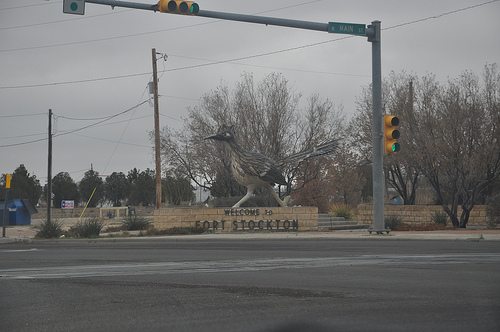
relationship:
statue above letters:
[207, 124, 344, 208] [196, 207, 300, 232]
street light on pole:
[383, 113, 400, 156] [86, 1, 392, 234]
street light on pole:
[159, 1, 199, 17] [86, 1, 392, 234]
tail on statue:
[273, 138, 339, 166] [207, 124, 344, 208]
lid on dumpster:
[21, 197, 39, 215] [1, 199, 38, 225]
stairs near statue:
[318, 210, 370, 232] [207, 124, 344, 208]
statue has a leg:
[207, 124, 344, 208] [232, 183, 257, 209]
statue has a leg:
[207, 124, 344, 208] [267, 184, 290, 208]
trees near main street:
[147, 62, 499, 228] [0, 235, 500, 331]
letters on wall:
[196, 207, 300, 232] [33, 206, 320, 231]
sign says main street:
[326, 22, 368, 36] [339, 24, 364, 32]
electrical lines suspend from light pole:
[2, 0, 499, 149] [151, 47, 164, 206]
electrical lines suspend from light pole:
[2, 0, 499, 149] [46, 108, 51, 217]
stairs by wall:
[318, 210, 370, 232] [33, 206, 320, 231]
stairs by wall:
[318, 210, 370, 232] [358, 201, 497, 227]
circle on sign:
[72, 1, 78, 12] [62, 1, 85, 15]